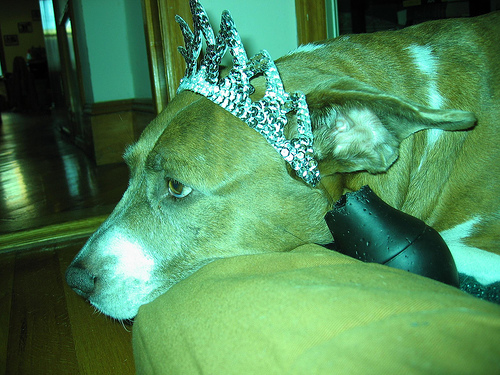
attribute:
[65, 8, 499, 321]
dog — brown, resting, sad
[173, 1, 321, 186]
tiara — silver, sequined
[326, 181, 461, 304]
toy — black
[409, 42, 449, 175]
patch — white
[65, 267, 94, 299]
nose — black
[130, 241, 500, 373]
couch — tan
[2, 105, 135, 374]
floor — wooden, brown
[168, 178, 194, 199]
eye — brown, open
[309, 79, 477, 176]
left ear — floppy